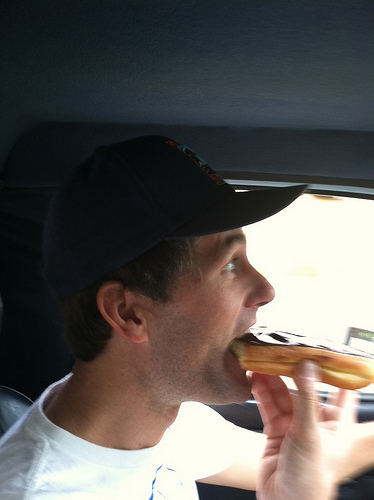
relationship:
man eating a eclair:
[8, 132, 358, 499] [228, 324, 374, 392]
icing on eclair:
[237, 329, 364, 358] [228, 324, 374, 392]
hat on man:
[41, 129, 309, 296] [8, 132, 358, 499]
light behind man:
[242, 188, 374, 348] [8, 132, 358, 499]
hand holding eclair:
[255, 360, 360, 499] [228, 324, 374, 392]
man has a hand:
[8, 132, 358, 499] [255, 360, 360, 499]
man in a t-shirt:
[8, 132, 358, 499] [6, 377, 236, 500]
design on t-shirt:
[145, 454, 181, 499] [6, 377, 236, 500]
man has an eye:
[8, 132, 358, 499] [218, 251, 243, 278]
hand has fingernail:
[255, 360, 360, 499] [299, 360, 315, 380]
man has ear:
[0, 131, 374, 500] [94, 277, 152, 348]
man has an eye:
[0, 131, 374, 500] [218, 251, 243, 278]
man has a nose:
[0, 131, 374, 500] [243, 262, 277, 311]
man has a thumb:
[0, 131, 374, 500] [291, 358, 323, 446]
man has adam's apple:
[8, 132, 358, 499] [152, 397, 188, 431]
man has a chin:
[0, 131, 374, 500] [217, 367, 255, 411]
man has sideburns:
[8, 132, 358, 499] [139, 271, 185, 318]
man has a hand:
[0, 131, 374, 500] [255, 360, 360, 499]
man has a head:
[8, 132, 358, 499] [47, 132, 273, 411]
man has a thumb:
[8, 132, 358, 499] [291, 358, 323, 446]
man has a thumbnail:
[8, 132, 358, 499] [297, 358, 319, 381]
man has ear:
[8, 132, 358, 499] [94, 277, 152, 348]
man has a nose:
[8, 132, 358, 499] [243, 262, 277, 311]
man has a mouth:
[8, 132, 358, 499] [226, 314, 264, 378]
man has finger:
[8, 132, 358, 499] [334, 384, 360, 420]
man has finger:
[8, 132, 358, 499] [250, 375, 275, 418]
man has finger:
[8, 132, 358, 499] [264, 367, 297, 415]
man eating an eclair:
[8, 132, 358, 499] [235, 328, 373, 400]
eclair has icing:
[235, 328, 373, 400] [237, 329, 364, 358]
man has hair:
[8, 132, 358, 499] [56, 237, 196, 368]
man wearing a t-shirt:
[8, 132, 358, 499] [6, 377, 236, 500]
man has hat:
[8, 132, 358, 499] [41, 129, 309, 296]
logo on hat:
[168, 136, 233, 192] [41, 129, 309, 296]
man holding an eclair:
[8, 132, 358, 499] [235, 328, 373, 400]